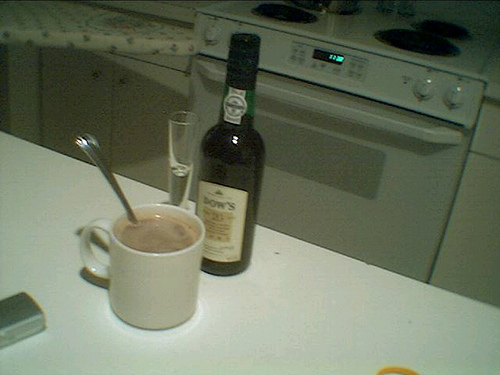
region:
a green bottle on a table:
[191, 27, 264, 277]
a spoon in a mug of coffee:
[75, 130, 138, 223]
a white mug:
[77, 200, 204, 330]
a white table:
[0, 131, 496, 371]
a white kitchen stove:
[178, 10, 496, 283]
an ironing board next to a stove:
[0, 3, 212, 64]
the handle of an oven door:
[192, 57, 463, 152]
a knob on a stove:
[409, 76, 435, 106]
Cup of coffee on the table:
[77, 198, 205, 333]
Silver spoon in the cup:
[69, 130, 139, 228]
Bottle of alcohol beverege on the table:
[196, 29, 268, 276]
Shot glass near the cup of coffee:
[163, 109, 200, 207]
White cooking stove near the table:
[189, 4, 495, 271]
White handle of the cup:
[72, 217, 112, 285]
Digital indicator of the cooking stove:
[306, 47, 345, 64]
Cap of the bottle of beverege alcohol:
[224, 31, 265, 53]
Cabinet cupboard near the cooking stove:
[37, 40, 193, 190]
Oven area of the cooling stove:
[184, 49, 466, 288]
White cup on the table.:
[75, 201, 205, 329]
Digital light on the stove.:
[306, 43, 342, 63]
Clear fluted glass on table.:
[161, 103, 201, 207]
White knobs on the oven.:
[410, 73, 466, 110]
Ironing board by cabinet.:
[0, 0, 197, 60]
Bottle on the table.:
[195, 26, 268, 278]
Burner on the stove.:
[373, 23, 458, 60]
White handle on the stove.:
[191, 49, 467, 150]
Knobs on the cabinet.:
[84, 65, 131, 86]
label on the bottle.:
[195, 178, 250, 266]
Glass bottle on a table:
[195, 30, 265, 275]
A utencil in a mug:
[74, 133, 138, 223]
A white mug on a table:
[78, 204, 205, 330]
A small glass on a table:
[166, 109, 196, 208]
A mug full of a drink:
[78, 203, 205, 331]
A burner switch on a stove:
[411, 76, 436, 102]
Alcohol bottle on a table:
[194, 34, 269, 277]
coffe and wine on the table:
[22, 11, 473, 360]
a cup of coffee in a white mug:
[69, 210, 207, 325]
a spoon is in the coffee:
[60, 135, 145, 218]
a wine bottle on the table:
[209, 26, 264, 276]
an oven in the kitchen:
[182, 11, 482, 146]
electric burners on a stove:
[375, 7, 473, 69]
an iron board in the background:
[6, 3, 231, 56]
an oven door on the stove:
[264, 77, 464, 262]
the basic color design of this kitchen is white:
[27, 13, 497, 340]